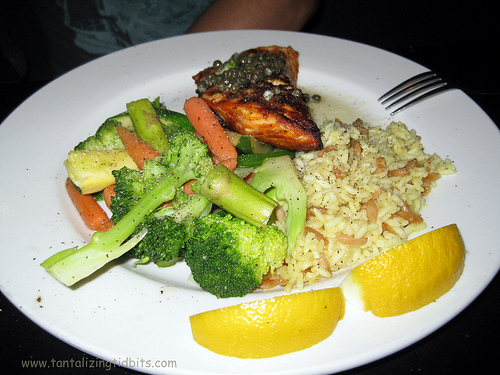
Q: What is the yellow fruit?
A: Lemons.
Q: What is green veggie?
A: Broccoli.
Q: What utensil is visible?
A: Fork.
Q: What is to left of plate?
A: Veggies.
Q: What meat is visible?
A: Chicken.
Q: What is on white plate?
A: Food.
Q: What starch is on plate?
A: Rice.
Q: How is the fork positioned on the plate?
A: Tines on edge of plate.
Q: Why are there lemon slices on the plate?
A: Flavoring.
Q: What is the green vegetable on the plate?
A: Broccoli.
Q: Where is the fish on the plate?
A: Beside the vegetables.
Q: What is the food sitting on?
A: White plate.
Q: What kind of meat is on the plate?
A: Fish.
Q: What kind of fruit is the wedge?
A: Lemon.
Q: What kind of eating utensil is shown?
A: Fork.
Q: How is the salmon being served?
A: Grilled.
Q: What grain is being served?
A: Rice.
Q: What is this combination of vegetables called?
A: Medley.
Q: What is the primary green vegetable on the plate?
A: Broccoli.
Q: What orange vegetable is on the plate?
A: Carrots.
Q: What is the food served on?
A: Plate.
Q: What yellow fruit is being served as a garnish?
A: Lemon.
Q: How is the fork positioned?
A: Face down on the plate.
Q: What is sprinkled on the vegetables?
A: Pepper.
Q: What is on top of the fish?
A: Pesto.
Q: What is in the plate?
A: Rice.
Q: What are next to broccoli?
A: Carrots.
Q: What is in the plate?
A: Lemon.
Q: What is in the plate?
A: Rice.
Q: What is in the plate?
A: Salmon.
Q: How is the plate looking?
A: Circular.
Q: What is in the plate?
A: Lemon pieces.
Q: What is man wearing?
A: Shirt.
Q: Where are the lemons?
A: On the plate.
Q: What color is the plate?
A: White.